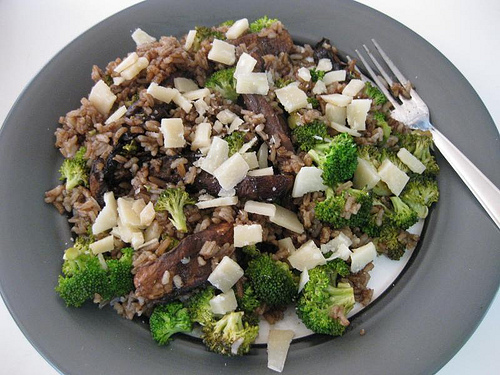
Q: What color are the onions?
A: White.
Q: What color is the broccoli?
A: Green.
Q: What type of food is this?
A: Chinese.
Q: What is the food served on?
A: A plate.